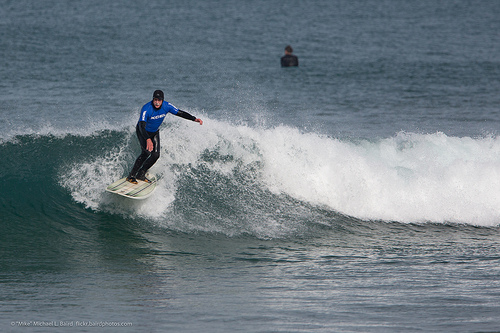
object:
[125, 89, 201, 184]
man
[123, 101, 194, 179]
wet suit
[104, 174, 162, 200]
surfboard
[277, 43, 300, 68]
man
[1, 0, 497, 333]
water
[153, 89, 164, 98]
hat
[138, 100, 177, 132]
rash guard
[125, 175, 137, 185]
bootie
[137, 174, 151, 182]
bootie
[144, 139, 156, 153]
hand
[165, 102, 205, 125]
arm